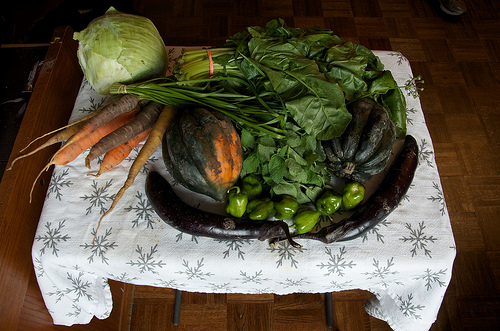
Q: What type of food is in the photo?
A: Vegetables.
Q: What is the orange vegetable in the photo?
A: Carrots.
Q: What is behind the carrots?
A: Lettuce.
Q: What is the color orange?
A: The carrots.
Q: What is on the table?
A: Collard greens.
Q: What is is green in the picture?
A: The cabbage.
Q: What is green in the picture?
A: The cabbage.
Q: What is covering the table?
A: Tablecloth.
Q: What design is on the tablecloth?
A: Snowflakes.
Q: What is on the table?
A: Vegetables.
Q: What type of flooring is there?
A: Wooden.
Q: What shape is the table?
A: Square.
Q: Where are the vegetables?
A: On the table.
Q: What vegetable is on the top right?
A: Spinach.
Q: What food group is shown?
A: Vegetables.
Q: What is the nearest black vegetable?
A: Eggplant.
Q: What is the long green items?
A: Scallions.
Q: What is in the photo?
A: Vegetables.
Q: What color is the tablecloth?
A: White.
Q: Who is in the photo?
A: Nobody.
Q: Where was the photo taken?
A: On a table.